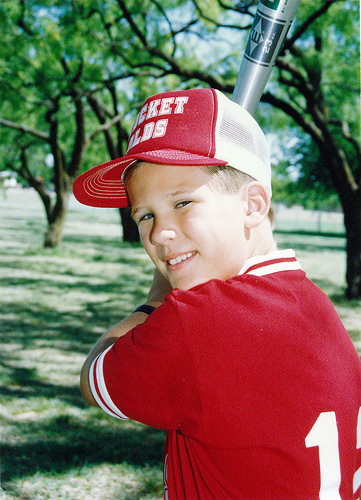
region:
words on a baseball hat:
[117, 94, 202, 152]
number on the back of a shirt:
[300, 390, 360, 499]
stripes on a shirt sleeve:
[86, 337, 131, 426]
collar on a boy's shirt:
[228, 244, 307, 285]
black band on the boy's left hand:
[126, 299, 157, 322]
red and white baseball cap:
[60, 80, 280, 215]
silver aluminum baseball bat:
[229, 0, 301, 117]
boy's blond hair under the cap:
[202, 164, 281, 231]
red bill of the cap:
[61, 147, 231, 210]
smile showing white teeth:
[163, 247, 197, 271]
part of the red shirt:
[174, 295, 203, 345]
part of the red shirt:
[228, 300, 259, 353]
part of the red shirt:
[142, 379, 184, 412]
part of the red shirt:
[213, 380, 248, 411]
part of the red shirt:
[324, 366, 347, 393]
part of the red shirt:
[176, 439, 199, 481]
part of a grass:
[124, 478, 131, 493]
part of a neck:
[224, 319, 226, 334]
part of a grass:
[88, 449, 104, 471]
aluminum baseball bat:
[232, 1, 300, 112]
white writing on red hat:
[124, 95, 190, 154]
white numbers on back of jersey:
[305, 407, 360, 499]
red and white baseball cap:
[71, 86, 271, 207]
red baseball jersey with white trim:
[88, 248, 360, 499]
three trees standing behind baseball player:
[0, 0, 359, 303]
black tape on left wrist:
[131, 303, 156, 314]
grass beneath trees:
[3, 207, 359, 497]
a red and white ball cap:
[73, 85, 276, 210]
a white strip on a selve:
[91, 337, 118, 421]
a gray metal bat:
[237, 1, 295, 102]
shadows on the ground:
[0, 265, 78, 480]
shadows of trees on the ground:
[0, 270, 77, 398]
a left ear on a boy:
[246, 181, 272, 229]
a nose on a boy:
[148, 218, 174, 253]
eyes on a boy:
[136, 197, 199, 220]